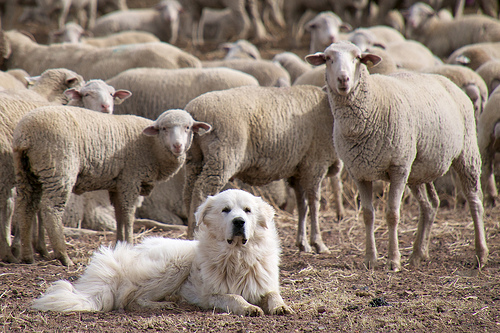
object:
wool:
[27, 108, 153, 182]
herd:
[0, 0, 497, 275]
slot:
[362, 285, 398, 321]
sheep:
[299, 36, 496, 274]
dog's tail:
[28, 239, 123, 311]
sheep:
[13, 62, 93, 111]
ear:
[188, 114, 213, 134]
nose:
[229, 213, 251, 231]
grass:
[285, 256, 500, 333]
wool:
[221, 90, 336, 179]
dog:
[26, 188, 313, 325]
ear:
[142, 125, 159, 140]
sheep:
[299, 9, 360, 49]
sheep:
[180, 71, 345, 253]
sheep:
[98, 65, 258, 118]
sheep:
[205, 53, 294, 86]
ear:
[192, 194, 215, 230]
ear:
[252, 195, 276, 230]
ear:
[305, 50, 329, 67]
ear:
[354, 48, 382, 68]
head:
[318, 38, 365, 98]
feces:
[369, 294, 389, 310]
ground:
[0, 193, 500, 331]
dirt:
[1, 202, 499, 332]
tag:
[196, 126, 207, 138]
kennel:
[1, 2, 500, 330]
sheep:
[9, 91, 217, 274]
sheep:
[1, 70, 134, 261]